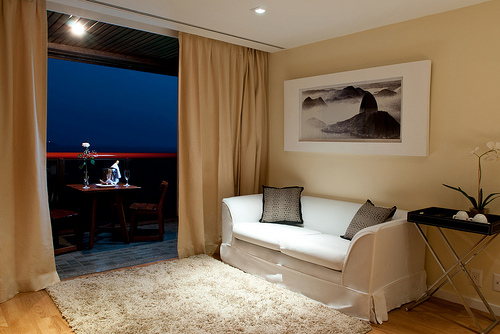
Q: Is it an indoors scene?
A: Yes, it is indoors.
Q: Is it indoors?
A: Yes, it is indoors.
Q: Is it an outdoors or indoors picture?
A: It is indoors.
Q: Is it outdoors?
A: No, it is indoors.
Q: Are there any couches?
A: Yes, there is a couch.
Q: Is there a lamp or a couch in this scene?
A: Yes, there is a couch.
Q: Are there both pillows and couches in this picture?
A: Yes, there are both a couch and a pillow.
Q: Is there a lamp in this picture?
A: No, there are no lamps.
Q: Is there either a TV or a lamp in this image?
A: No, there are no lamps or televisions.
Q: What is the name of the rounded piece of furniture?
A: The piece of furniture is a couch.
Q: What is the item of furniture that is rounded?
A: The piece of furniture is a couch.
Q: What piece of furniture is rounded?
A: The piece of furniture is a couch.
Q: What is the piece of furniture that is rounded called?
A: The piece of furniture is a couch.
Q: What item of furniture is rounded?
A: The piece of furniture is a couch.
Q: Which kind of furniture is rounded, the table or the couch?
A: The couch is rounded.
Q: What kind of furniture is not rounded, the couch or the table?
A: The table is not rounded.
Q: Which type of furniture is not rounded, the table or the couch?
A: The table is not rounded.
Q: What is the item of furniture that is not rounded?
A: The piece of furniture is a table.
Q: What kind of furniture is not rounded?
A: The furniture is a table.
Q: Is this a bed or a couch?
A: This is a couch.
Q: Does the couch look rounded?
A: Yes, the couch is rounded.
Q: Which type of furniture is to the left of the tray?
A: The piece of furniture is a couch.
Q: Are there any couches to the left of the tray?
A: Yes, there is a couch to the left of the tray.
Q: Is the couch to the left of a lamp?
A: No, the couch is to the left of the tray.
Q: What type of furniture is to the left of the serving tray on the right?
A: The piece of furniture is a couch.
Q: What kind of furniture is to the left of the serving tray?
A: The piece of furniture is a couch.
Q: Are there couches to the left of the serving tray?
A: Yes, there is a couch to the left of the serving tray.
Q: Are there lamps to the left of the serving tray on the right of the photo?
A: No, there is a couch to the left of the food tray.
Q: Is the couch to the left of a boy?
A: No, the couch is to the left of the serving tray.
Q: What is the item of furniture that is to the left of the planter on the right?
A: The piece of furniture is a couch.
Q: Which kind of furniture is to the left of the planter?
A: The piece of furniture is a couch.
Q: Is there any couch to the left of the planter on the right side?
A: Yes, there is a couch to the left of the planter.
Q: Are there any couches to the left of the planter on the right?
A: Yes, there is a couch to the left of the planter.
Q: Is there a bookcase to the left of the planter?
A: No, there is a couch to the left of the planter.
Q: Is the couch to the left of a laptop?
A: No, the couch is to the left of a planter.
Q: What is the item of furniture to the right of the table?
A: The piece of furniture is a couch.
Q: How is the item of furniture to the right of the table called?
A: The piece of furniture is a couch.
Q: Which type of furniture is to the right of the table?
A: The piece of furniture is a couch.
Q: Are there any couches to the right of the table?
A: Yes, there is a couch to the right of the table.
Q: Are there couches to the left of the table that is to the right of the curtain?
A: No, the couch is to the right of the table.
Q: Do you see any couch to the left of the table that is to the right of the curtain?
A: No, the couch is to the right of the table.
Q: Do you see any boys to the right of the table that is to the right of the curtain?
A: No, there is a couch to the right of the table.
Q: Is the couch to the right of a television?
A: No, the couch is to the right of a table.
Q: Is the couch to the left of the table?
A: No, the couch is to the right of the table.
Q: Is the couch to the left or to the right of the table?
A: The couch is to the right of the table.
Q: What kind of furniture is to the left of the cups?
A: The piece of furniture is a couch.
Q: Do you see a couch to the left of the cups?
A: Yes, there is a couch to the left of the cups.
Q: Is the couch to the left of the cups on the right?
A: Yes, the couch is to the left of the cups.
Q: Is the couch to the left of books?
A: No, the couch is to the left of the cups.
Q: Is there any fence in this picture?
A: No, there are no fences.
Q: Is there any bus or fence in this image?
A: No, there are no fences or buses.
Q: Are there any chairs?
A: Yes, there is a chair.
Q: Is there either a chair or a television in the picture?
A: Yes, there is a chair.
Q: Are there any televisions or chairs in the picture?
A: Yes, there is a chair.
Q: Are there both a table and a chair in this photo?
A: Yes, there are both a chair and a table.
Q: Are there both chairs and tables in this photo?
A: Yes, there are both a chair and a table.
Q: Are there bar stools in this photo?
A: No, there are no bar stools.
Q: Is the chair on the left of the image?
A: Yes, the chair is on the left of the image.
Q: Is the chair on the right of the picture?
A: No, the chair is on the left of the image.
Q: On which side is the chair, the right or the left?
A: The chair is on the left of the image.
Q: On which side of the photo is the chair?
A: The chair is on the left of the image.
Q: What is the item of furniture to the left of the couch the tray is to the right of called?
A: The piece of furniture is a chair.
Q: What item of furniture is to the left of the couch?
A: The piece of furniture is a chair.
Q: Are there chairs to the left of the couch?
A: Yes, there is a chair to the left of the couch.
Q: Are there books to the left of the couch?
A: No, there is a chair to the left of the couch.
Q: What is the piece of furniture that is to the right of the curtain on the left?
A: The piece of furniture is a chair.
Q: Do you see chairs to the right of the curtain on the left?
A: Yes, there is a chair to the right of the curtain.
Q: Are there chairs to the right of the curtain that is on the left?
A: Yes, there is a chair to the right of the curtain.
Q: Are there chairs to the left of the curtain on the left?
A: No, the chair is to the right of the curtain.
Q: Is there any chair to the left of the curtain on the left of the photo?
A: No, the chair is to the right of the curtain.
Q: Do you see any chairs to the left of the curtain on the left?
A: No, the chair is to the right of the curtain.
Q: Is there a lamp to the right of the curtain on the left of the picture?
A: No, there is a chair to the right of the curtain.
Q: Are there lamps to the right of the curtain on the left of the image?
A: No, there is a chair to the right of the curtain.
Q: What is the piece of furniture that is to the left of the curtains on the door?
A: The piece of furniture is a chair.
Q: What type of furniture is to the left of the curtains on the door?
A: The piece of furniture is a chair.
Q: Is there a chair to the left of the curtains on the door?
A: Yes, there is a chair to the left of the curtains.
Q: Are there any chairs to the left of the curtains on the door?
A: Yes, there is a chair to the left of the curtains.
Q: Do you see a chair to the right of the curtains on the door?
A: No, the chair is to the left of the curtains.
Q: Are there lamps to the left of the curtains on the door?
A: No, there is a chair to the left of the curtains.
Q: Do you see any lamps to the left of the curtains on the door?
A: No, there is a chair to the left of the curtains.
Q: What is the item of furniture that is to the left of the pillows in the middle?
A: The piece of furniture is a chair.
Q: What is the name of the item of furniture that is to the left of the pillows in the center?
A: The piece of furniture is a chair.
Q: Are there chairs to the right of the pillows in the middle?
A: No, the chair is to the left of the pillows.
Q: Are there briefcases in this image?
A: No, there are no briefcases.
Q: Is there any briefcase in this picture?
A: No, there are no briefcases.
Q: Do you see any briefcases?
A: No, there are no briefcases.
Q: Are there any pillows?
A: Yes, there is a pillow.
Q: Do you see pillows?
A: Yes, there is a pillow.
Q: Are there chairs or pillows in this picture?
A: Yes, there is a pillow.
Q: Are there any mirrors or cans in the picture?
A: No, there are no mirrors or cans.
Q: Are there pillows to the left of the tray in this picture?
A: Yes, there is a pillow to the left of the tray.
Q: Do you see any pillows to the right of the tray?
A: No, the pillow is to the left of the tray.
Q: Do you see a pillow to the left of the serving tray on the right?
A: Yes, there is a pillow to the left of the food tray.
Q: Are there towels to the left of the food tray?
A: No, there is a pillow to the left of the food tray.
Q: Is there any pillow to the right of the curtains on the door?
A: Yes, there is a pillow to the right of the curtains.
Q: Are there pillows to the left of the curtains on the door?
A: No, the pillow is to the right of the curtains.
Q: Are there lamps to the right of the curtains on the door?
A: No, there is a pillow to the right of the curtains.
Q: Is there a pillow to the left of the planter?
A: Yes, there is a pillow to the left of the planter.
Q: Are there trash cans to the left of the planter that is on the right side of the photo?
A: No, there is a pillow to the left of the planter.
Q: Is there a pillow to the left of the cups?
A: Yes, there is a pillow to the left of the cups.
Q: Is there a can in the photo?
A: No, there are no cans.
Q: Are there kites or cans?
A: No, there are no cans or kites.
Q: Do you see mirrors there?
A: No, there are no mirrors.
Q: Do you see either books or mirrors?
A: No, there are no mirrors or books.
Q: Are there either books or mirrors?
A: No, there are no mirrors or books.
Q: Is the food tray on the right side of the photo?
A: Yes, the food tray is on the right of the image.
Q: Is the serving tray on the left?
A: No, the serving tray is on the right of the image.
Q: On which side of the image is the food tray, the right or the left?
A: The food tray is on the right of the image.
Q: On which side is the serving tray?
A: The serving tray is on the right of the image.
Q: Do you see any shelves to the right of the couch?
A: No, there is a serving tray to the right of the couch.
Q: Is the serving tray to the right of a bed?
A: No, the serving tray is to the right of the couch.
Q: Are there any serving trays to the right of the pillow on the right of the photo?
A: Yes, there is a serving tray to the right of the pillow.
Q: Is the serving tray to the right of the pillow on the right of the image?
A: Yes, the serving tray is to the right of the pillow.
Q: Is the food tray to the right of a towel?
A: No, the food tray is to the right of the pillow.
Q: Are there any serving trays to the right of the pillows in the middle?
A: Yes, there is a serving tray to the right of the pillows.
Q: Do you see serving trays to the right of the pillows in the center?
A: Yes, there is a serving tray to the right of the pillows.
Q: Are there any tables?
A: Yes, there is a table.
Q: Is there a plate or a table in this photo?
A: Yes, there is a table.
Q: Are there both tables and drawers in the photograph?
A: No, there is a table but no drawers.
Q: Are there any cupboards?
A: No, there are no cupboards.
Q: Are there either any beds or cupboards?
A: No, there are no cupboards or beds.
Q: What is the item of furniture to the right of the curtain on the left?
A: The piece of furniture is a table.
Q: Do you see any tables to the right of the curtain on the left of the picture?
A: Yes, there is a table to the right of the curtain.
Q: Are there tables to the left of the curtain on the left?
A: No, the table is to the right of the curtain.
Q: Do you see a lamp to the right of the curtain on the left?
A: No, there is a table to the right of the curtain.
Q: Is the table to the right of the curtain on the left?
A: Yes, the table is to the right of the curtain.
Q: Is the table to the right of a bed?
A: No, the table is to the right of the curtain.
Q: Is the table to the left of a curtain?
A: No, the table is to the right of a curtain.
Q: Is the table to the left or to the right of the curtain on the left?
A: The table is to the right of the curtain.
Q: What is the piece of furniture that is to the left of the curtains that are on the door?
A: The piece of furniture is a table.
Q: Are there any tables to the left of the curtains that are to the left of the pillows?
A: Yes, there is a table to the left of the curtains.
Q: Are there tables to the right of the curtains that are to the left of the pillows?
A: No, the table is to the left of the curtains.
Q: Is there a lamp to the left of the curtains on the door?
A: No, there is a table to the left of the curtains.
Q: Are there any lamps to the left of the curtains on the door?
A: No, there is a table to the left of the curtains.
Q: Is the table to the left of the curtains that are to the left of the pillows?
A: Yes, the table is to the left of the curtains.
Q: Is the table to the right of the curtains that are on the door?
A: No, the table is to the left of the curtains.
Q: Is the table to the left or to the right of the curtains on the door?
A: The table is to the left of the curtains.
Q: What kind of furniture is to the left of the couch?
A: The piece of furniture is a table.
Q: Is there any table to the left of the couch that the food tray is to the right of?
A: Yes, there is a table to the left of the couch.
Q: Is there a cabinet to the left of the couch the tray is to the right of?
A: No, there is a table to the left of the couch.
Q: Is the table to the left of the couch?
A: Yes, the table is to the left of the couch.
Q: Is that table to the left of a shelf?
A: No, the table is to the left of the couch.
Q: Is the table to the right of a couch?
A: No, the table is to the left of a couch.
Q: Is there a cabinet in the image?
A: No, there are no cabinets.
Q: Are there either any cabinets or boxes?
A: No, there are no cabinets or boxes.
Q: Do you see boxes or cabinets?
A: No, there are no cabinets or boxes.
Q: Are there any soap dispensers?
A: No, there are no soap dispensers.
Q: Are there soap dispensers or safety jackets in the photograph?
A: No, there are no soap dispensers or safety jackets.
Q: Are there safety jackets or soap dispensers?
A: No, there are no soap dispensers or safety jackets.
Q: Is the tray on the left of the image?
A: No, the tray is on the right of the image.